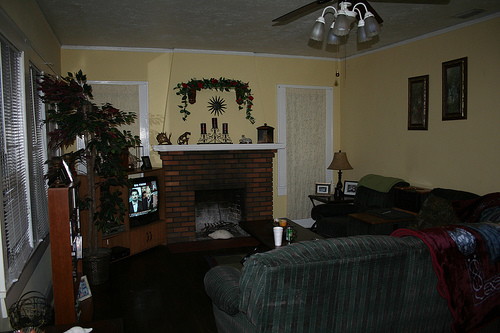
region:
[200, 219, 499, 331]
blue couch with lite blue lines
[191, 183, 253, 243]
fire place opening with ashes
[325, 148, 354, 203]
table lamp with shade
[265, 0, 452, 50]
ceiling fan with lights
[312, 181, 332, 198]
photo in a frame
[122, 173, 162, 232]
television in an entertainment center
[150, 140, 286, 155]
white fireplace mantel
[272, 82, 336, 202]
white trimmed window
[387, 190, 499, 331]
blanket draped over the couch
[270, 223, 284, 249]
white styrofoam cup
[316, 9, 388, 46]
White light fixture on ceiling fan.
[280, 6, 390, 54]
Ceiling fan in the middle of the room.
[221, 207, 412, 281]
Grayish blue couch in room.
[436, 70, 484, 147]
Picture hanging on wall.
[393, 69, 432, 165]
Picture hanging on wall.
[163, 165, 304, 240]
Brick fireplace in room.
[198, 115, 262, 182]
Candles on top of the mantle.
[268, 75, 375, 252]
Long curtain on window.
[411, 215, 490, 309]
Red blanket over back of couch.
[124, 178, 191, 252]
TV in tv stand.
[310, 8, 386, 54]
this is a light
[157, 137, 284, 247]
this is a fireplace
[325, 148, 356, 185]
this is a lamp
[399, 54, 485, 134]
these are pictures on the wall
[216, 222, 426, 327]
this is a striped couch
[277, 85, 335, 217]
These are floor to ceiling drapes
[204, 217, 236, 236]
this is a firelace grate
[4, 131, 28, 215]
these are venition blinds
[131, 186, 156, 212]
this is a tv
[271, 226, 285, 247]
this is a white cup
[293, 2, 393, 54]
Ceiling lights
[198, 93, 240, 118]
A sun wall hanging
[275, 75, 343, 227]
A window with a curtain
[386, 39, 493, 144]
Two pictures on a wall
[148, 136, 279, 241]
A brick fireplace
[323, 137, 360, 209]
A lamp on a table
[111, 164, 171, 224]
A television turned on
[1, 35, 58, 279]
Windows with Venetian blinds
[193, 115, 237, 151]
A set of three candles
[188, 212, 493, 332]
A striped velour couch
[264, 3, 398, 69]
lights on a ceiling fan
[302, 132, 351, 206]
a small table lamp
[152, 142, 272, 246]
a brick fire place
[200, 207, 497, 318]
a green striped green couch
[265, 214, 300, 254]
white cup on the table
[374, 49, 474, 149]
pictures on the wall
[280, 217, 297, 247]
a green soda can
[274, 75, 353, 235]
a beige long curtain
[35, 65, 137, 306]
a tall potted tree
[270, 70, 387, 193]
the windows border is white